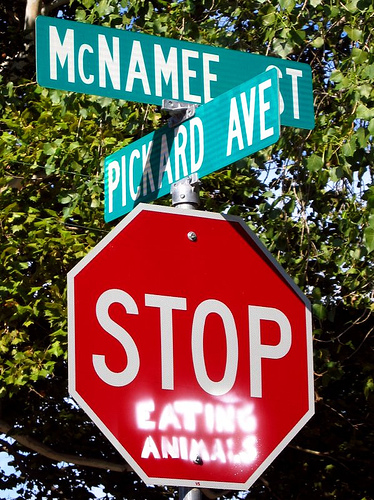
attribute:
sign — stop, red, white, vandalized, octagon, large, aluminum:
[62, 197, 316, 494]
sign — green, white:
[99, 67, 285, 228]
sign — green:
[33, 12, 321, 136]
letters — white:
[91, 281, 295, 402]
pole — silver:
[161, 96, 202, 499]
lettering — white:
[105, 78, 275, 213]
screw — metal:
[189, 450, 208, 469]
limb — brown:
[3, 416, 135, 484]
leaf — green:
[305, 146, 331, 192]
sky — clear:
[1, 3, 367, 495]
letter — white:
[90, 281, 147, 391]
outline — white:
[63, 202, 316, 494]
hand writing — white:
[127, 392, 264, 479]